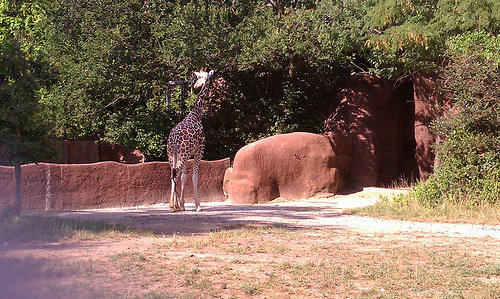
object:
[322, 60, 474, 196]
cave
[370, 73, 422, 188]
an entrance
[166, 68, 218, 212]
giraffe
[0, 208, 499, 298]
grass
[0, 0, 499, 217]
forest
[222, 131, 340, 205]
wall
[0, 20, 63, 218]
tree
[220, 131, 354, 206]
rock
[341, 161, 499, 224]
bush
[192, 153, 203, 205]
leg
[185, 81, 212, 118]
neck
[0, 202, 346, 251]
shadows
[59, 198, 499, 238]
ground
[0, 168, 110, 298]
dust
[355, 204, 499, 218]
grass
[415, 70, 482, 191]
wall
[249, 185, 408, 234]
pathway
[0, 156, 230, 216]
wall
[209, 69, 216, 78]
ear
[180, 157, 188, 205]
leg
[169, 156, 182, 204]
leg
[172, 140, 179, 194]
tail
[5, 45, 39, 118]
leaves